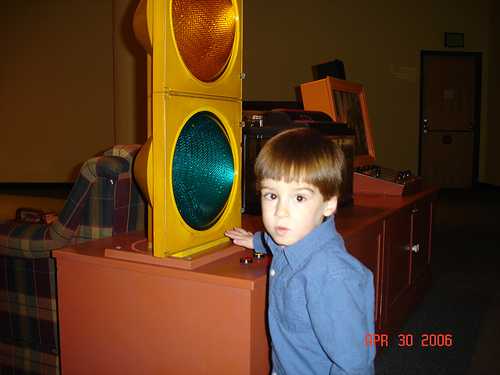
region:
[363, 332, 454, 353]
apr 30 2006 is the date stamp on the photograph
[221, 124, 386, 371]
The little boy is standing in front of a stop light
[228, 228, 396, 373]
the shirt the little boy is wearing is a blue button down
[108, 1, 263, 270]
two thirds of the stop light that the boy is looking at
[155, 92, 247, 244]
the green light on the bottom of the stop light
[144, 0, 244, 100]
the yellow light of the stop light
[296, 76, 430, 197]
the computer is sitting on a table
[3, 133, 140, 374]
a chair in the back behind the table the computer and stop light are on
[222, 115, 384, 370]
the little boy has brown eyes and brown hair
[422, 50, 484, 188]
this door is used to enter or leave the room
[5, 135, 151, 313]
the couch is plaid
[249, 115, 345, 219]
the boy has straight brown hair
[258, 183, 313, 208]
the boy has brown eyes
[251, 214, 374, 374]
the boy is wearing a blue shirt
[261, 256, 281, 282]
the shirt has white buttons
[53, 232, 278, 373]
the cabinet is a burnt orange color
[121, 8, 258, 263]
there is a stoplight in the room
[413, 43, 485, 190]
the door has a silver bar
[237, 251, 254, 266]
the button is red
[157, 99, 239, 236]
this light is green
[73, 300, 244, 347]
solid orange walls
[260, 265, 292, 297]
white button on blue shirt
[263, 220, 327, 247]
red lips on boy's face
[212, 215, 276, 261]
boy's fingers on surface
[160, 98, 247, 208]
shiny green traffic light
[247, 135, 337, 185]
boy's brown bangs on face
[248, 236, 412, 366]
long sleeve blue shirt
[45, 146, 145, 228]
arm of plaid sofa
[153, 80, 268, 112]
long line in yellow traffic light signal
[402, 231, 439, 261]
white opener on brown surface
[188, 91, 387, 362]
A boy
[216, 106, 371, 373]
A boy wearing a blue shirt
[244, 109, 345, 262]
The head of a boy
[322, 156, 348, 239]
The ear of a boy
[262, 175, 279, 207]
The right eye of a boy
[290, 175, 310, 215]
The left eye of a boy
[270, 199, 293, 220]
The nose of a boy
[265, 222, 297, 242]
The mouth of a boy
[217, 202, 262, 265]
The hand of a boy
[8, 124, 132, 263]
A plaid chair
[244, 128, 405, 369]
the boy by the traffic light on table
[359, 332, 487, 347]
the date the photo was taken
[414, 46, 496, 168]
the door in the back ground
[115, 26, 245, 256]
the yellwo traffic lights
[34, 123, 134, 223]
the plaid couch in the back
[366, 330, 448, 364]
april 30th 2006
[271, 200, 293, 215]
the nose of the boy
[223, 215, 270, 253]
the hand of the boy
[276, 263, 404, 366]
the shirt of the boy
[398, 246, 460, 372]
the floor in the scene